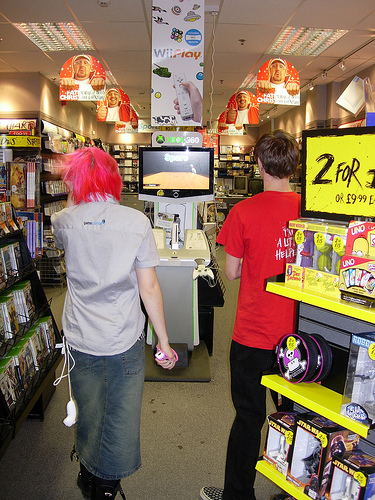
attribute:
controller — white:
[56, 332, 79, 429]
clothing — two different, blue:
[46, 186, 169, 484]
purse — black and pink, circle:
[273, 331, 318, 382]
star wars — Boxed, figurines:
[256, 406, 373, 499]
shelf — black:
[275, 262, 326, 388]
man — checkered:
[214, 127, 303, 499]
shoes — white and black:
[200, 482, 230, 498]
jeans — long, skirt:
[56, 341, 146, 472]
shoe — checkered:
[198, 486, 239, 498]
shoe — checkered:
[77, 466, 130, 499]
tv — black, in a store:
[130, 136, 216, 205]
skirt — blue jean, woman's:
[73, 341, 169, 465]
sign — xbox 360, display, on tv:
[149, 128, 205, 146]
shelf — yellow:
[257, 365, 374, 443]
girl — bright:
[46, 144, 173, 498]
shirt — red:
[218, 186, 331, 359]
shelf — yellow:
[254, 354, 374, 440]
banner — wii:
[124, 9, 227, 129]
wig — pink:
[65, 147, 124, 203]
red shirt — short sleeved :
[215, 189, 300, 349]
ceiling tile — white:
[222, 18, 249, 42]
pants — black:
[212, 314, 278, 491]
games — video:
[3, 227, 69, 443]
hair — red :
[61, 146, 125, 203]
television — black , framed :
[135, 142, 221, 203]